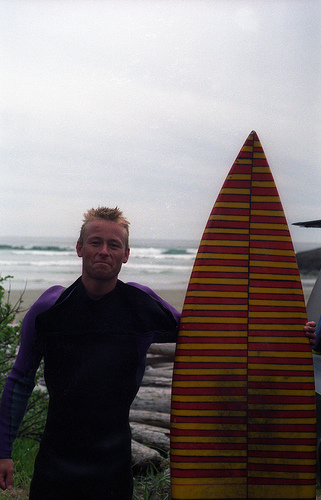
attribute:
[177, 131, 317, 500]
surfboard — multicolored, colorful, dirty, striped, upright, red, yellow, large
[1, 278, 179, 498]
wetsuit — purple, black, gray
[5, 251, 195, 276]
waves — calm, foaming, blue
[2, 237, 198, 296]
ocean — calm, distant, blue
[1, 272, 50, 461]
shrubbery — green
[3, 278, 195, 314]
sand — wet, smooth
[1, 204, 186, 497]
man — frowning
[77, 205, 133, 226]
hair — spiky, blonde, blond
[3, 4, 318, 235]
sky — overcast, cloudy, gray, blue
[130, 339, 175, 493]
wood — grey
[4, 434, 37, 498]
grass — green